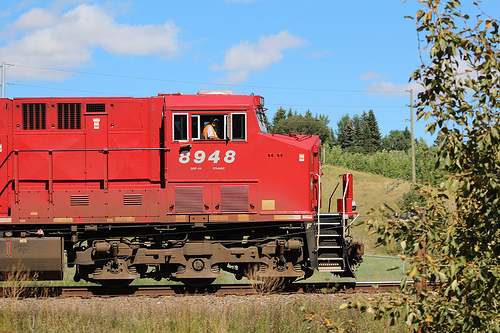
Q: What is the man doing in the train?
A: Driving the train.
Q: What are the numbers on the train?
A: 8948.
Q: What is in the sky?
A: White clouds.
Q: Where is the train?
A: On railway tracks.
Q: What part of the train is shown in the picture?
A: Head.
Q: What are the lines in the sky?
A: Electric wires.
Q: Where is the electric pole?
A: On a hill.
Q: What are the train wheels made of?
A: Metal.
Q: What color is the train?
A: Red.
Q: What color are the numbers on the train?
A: White.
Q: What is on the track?
A: A red engine.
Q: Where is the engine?
A: On a track.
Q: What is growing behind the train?
A: Trees.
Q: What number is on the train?
A: 8948.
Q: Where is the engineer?
A: In the train.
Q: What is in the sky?
A: Clouds.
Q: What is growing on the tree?
A: Leaves.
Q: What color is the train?
A: Red.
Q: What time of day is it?
A: Daylight.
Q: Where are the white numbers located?
A: Below the window.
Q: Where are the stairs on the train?
A: In the front.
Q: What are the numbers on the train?
A: 8948.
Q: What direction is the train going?
A: Right.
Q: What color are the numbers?
A: White.